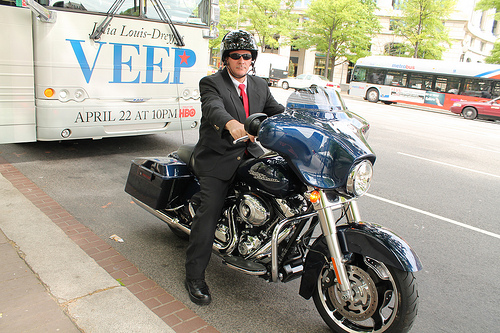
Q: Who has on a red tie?
A: The man.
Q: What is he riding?
A: A motorcycle.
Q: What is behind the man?
A: A bus.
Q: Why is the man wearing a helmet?
A: For safety.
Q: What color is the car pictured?
A: White.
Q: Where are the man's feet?
A: On the pavement.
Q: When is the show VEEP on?
A: April 22, 10 PM.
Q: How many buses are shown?
A: Two.